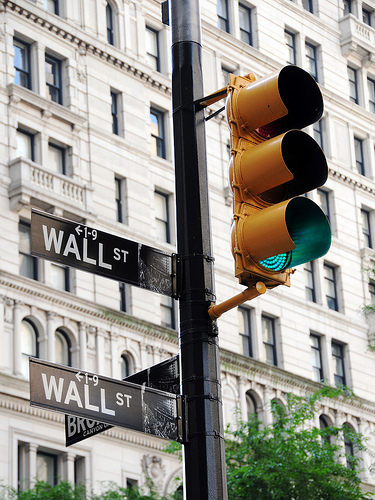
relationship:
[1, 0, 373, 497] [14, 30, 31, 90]
building has window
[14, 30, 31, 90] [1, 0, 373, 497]
window has building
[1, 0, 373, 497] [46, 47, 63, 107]
building has window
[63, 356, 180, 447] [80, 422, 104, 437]
sign has word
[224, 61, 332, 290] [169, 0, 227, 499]
stop light on pole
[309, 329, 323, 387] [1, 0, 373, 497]
window on building